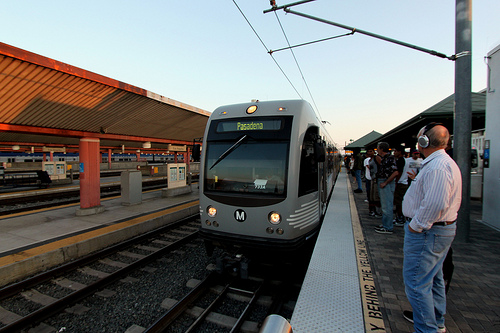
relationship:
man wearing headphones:
[391, 110, 473, 332] [417, 124, 439, 149]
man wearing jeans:
[401, 122, 464, 332] [398, 212, 458, 331]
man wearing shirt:
[401, 122, 464, 332] [391, 154, 451, 229]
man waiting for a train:
[401, 122, 464, 332] [190, 89, 344, 248]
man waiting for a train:
[374, 141, 399, 234] [190, 89, 344, 248]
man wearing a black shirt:
[376, 135, 401, 240] [376, 151, 398, 184]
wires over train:
[221, 0, 348, 154] [196, 95, 345, 294]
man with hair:
[401, 122, 464, 332] [420, 126, 448, 145]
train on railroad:
[196, 98, 343, 245] [0, 223, 320, 328]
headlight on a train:
[205, 204, 218, 218] [190, 89, 344, 248]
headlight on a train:
[267, 211, 282, 226] [190, 89, 344, 248]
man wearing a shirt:
[401, 122, 464, 332] [400, 152, 464, 223]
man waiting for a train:
[401, 122, 464, 332] [192, 95, 344, 272]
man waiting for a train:
[374, 141, 399, 234] [192, 95, 344, 272]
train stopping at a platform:
[196, 82, 343, 259] [288, 152, 498, 324]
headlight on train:
[267, 211, 282, 226] [190, 89, 344, 248]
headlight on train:
[205, 204, 218, 218] [190, 89, 344, 248]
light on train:
[245, 104, 258, 114] [190, 89, 344, 248]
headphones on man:
[417, 122, 443, 148] [401, 122, 464, 332]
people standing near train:
[354, 122, 420, 227] [196, 97, 341, 255]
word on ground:
[362, 282, 382, 321] [284, 162, 484, 332]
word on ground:
[356, 238, 385, 331] [284, 162, 484, 332]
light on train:
[274, 104, 287, 116] [196, 98, 343, 245]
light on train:
[242, 104, 257, 115] [196, 98, 343, 245]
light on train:
[216, 106, 231, 121] [196, 98, 343, 245]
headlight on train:
[267, 211, 282, 226] [196, 98, 343, 245]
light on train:
[245, 104, 258, 114] [196, 97, 341, 255]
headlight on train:
[205, 204, 218, 218] [196, 97, 341, 255]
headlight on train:
[267, 211, 282, 226] [196, 97, 341, 255]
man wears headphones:
[401, 122, 464, 332] [402, 110, 454, 153]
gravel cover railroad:
[21, 237, 209, 324] [0, 223, 320, 328]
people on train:
[353, 139, 423, 226] [196, 97, 341, 255]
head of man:
[413, 121, 452, 155] [401, 122, 464, 332]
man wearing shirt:
[401, 122, 464, 332] [401, 147, 461, 232]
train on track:
[196, 98, 343, 245] [87, 240, 241, 326]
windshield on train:
[200, 110, 296, 208] [196, 102, 343, 237]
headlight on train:
[270, 207, 282, 227] [196, 102, 343, 237]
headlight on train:
[206, 202, 219, 220] [196, 102, 343, 237]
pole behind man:
[453, 0, 471, 246] [401, 122, 464, 332]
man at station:
[401, 122, 464, 332] [338, 40, 498, 331]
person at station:
[362, 149, 374, 222] [338, 40, 498, 331]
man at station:
[374, 141, 399, 234] [338, 40, 498, 331]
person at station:
[348, 151, 355, 181] [338, 40, 498, 331]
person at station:
[403, 147, 421, 185] [338, 40, 498, 331]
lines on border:
[1, 197, 201, 266] [0, 199, 199, 285]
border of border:
[0, 199, 199, 285] [0, 199, 199, 285]